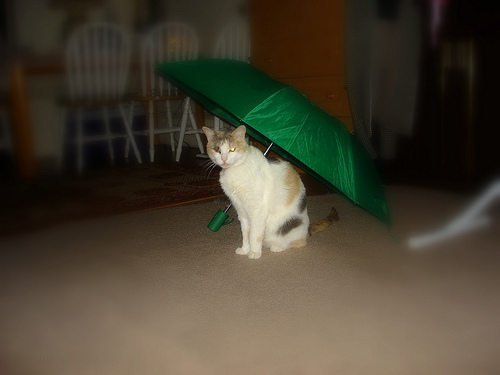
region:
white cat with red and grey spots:
[195, 120, 318, 260]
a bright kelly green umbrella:
[169, 56, 391, 226]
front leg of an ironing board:
[412, 161, 498, 263]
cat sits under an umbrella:
[149, 58, 389, 251]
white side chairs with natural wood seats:
[61, 14, 258, 166]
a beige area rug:
[1, 191, 498, 372]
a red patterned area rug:
[0, 155, 229, 234]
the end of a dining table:
[6, 50, 84, 190]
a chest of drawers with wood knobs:
[248, 6, 368, 146]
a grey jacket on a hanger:
[339, 9, 421, 163]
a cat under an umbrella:
[145, 44, 404, 271]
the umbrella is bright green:
[151, 47, 401, 245]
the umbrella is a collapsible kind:
[149, 48, 398, 245]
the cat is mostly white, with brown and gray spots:
[195, 117, 344, 260]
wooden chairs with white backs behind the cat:
[49, 11, 261, 168]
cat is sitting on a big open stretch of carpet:
[0, 176, 497, 369]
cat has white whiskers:
[195, 122, 252, 182]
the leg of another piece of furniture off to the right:
[398, 153, 498, 253]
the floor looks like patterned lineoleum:
[1, 143, 247, 223]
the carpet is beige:
[4, 218, 494, 374]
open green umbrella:
[149, 42, 406, 234]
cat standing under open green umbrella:
[151, 50, 398, 269]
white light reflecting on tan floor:
[394, 167, 488, 270]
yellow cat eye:
[225, 144, 238, 156]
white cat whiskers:
[198, 151, 220, 179]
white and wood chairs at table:
[51, 11, 210, 177]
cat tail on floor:
[308, 196, 341, 241]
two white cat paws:
[231, 240, 267, 264]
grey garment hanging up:
[336, 3, 431, 165]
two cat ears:
[194, 121, 250, 138]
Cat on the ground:
[197, 119, 347, 262]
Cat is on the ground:
[195, 123, 345, 264]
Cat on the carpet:
[199, 119, 342, 259]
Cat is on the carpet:
[199, 122, 350, 253]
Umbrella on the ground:
[147, 49, 403, 251]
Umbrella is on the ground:
[147, 52, 398, 243]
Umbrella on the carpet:
[150, 55, 395, 240]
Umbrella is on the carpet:
[146, 46, 401, 243]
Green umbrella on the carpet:
[152, 52, 402, 249]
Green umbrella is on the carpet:
[145, 51, 401, 237]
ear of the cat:
[232, 125, 244, 139]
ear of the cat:
[207, 118, 214, 137]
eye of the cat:
[229, 143, 238, 158]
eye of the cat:
[206, 145, 221, 153]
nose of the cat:
[225, 156, 230, 162]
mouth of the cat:
[224, 163, 230, 173]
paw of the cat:
[230, 246, 247, 256]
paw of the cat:
[250, 250, 260, 260]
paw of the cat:
[271, 238, 285, 255]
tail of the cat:
[312, 216, 337, 238]